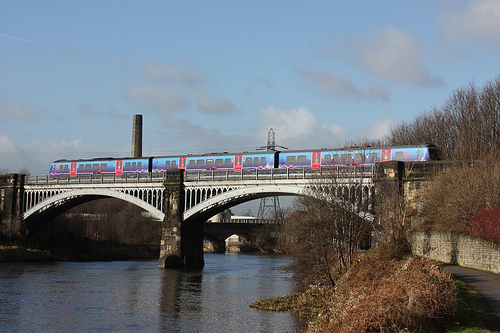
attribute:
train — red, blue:
[47, 141, 436, 174]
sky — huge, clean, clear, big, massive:
[0, 1, 499, 139]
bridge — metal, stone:
[0, 166, 416, 255]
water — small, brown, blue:
[0, 248, 319, 332]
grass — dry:
[339, 267, 431, 325]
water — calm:
[12, 249, 337, 330]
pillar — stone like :
[162, 165, 178, 266]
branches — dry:
[432, 84, 499, 202]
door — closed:
[232, 151, 244, 176]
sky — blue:
[4, 5, 494, 175]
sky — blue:
[6, 9, 498, 163]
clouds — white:
[142, 60, 402, 143]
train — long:
[30, 145, 440, 181]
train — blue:
[46, 144, 429, 187]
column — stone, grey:
[161, 169, 191, 283]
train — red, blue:
[35, 142, 431, 185]